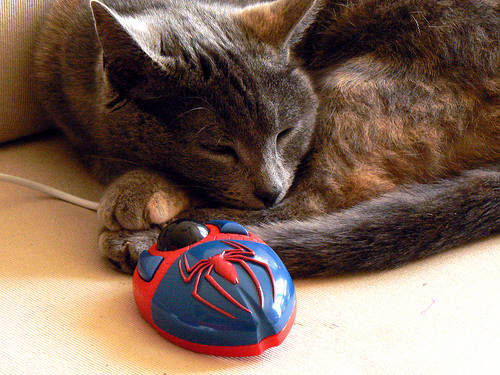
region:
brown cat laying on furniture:
[23, 2, 498, 272]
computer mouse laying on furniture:
[111, 212, 344, 361]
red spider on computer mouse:
[168, 231, 286, 333]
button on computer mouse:
[133, 247, 163, 291]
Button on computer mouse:
[206, 217, 264, 236]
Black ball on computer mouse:
[153, 215, 219, 254]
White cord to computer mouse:
[1, 155, 216, 244]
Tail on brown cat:
[5, 2, 498, 367]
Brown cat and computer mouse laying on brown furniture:
[14, 9, 431, 360]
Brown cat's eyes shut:
[167, 105, 327, 200]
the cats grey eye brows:
[165, 95, 225, 145]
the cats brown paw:
[95, 165, 185, 230]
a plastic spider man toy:
[131, 215, 292, 355]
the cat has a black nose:
[250, 185, 280, 205]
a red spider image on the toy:
[175, 236, 275, 316]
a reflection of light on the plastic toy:
[251, 251, 286, 316]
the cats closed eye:
[197, 140, 232, 155]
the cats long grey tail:
[295, 165, 495, 277]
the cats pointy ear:
[90, 0, 163, 93]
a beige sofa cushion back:
[0, 1, 48, 142]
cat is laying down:
[34, 6, 466, 342]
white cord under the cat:
[6, 142, 134, 258]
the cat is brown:
[36, 32, 498, 297]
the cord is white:
[7, 151, 154, 306]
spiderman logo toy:
[114, 198, 300, 370]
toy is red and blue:
[156, 237, 301, 349]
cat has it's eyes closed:
[180, 93, 335, 205]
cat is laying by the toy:
[25, 4, 498, 374]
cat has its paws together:
[84, 154, 186, 293]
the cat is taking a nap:
[20, 3, 495, 325]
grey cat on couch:
[26, 5, 483, 304]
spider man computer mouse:
[133, 219, 283, 351]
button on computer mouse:
[219, 214, 250, 234]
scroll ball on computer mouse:
[159, 217, 204, 245]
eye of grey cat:
[198, 130, 243, 175]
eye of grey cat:
[271, 115, 303, 152]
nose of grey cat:
[253, 182, 281, 212]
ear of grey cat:
[274, 2, 324, 87]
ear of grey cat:
[83, 0, 168, 79]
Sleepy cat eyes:
[185, 109, 312, 162]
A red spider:
[176, 238, 290, 320]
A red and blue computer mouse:
[123, 217, 307, 360]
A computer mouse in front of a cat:
[94, 80, 318, 374]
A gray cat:
[68, 2, 342, 213]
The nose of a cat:
[239, 162, 299, 212]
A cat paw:
[91, 165, 188, 234]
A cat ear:
[81, 2, 183, 109]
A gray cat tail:
[303, 165, 499, 282]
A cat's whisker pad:
[189, 163, 269, 217]